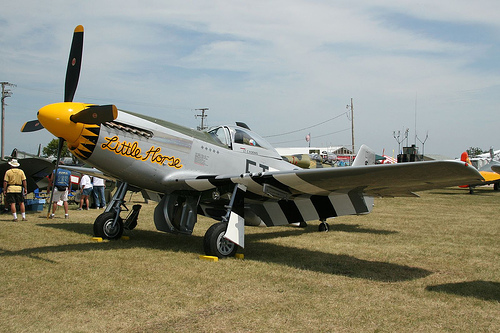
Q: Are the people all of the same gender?
A: No, they are both male and female.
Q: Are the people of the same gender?
A: No, they are both male and female.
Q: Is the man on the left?
A: Yes, the man is on the left of the image.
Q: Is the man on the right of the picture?
A: No, the man is on the left of the image.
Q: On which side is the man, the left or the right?
A: The man is on the left of the image.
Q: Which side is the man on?
A: The man is on the left of the image.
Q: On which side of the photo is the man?
A: The man is on the left of the image.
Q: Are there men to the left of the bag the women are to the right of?
A: Yes, there is a man to the left of the bag.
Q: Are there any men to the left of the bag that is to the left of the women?
A: Yes, there is a man to the left of the bag.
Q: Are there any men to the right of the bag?
A: No, the man is to the left of the bag.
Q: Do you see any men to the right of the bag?
A: No, the man is to the left of the bag.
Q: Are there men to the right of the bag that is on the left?
A: No, the man is to the left of the bag.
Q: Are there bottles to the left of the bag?
A: No, there is a man to the left of the bag.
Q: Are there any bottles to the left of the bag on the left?
A: No, there is a man to the left of the bag.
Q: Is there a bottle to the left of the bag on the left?
A: No, there is a man to the left of the bag.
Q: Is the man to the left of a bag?
A: Yes, the man is to the left of a bag.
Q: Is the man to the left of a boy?
A: No, the man is to the left of a bag.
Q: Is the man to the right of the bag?
A: No, the man is to the left of the bag.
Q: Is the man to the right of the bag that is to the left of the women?
A: No, the man is to the left of the bag.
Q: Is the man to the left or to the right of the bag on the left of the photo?
A: The man is to the left of the bag.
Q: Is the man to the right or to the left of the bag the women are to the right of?
A: The man is to the left of the bag.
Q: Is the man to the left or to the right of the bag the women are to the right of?
A: The man is to the left of the bag.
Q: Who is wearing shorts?
A: The man is wearing shorts.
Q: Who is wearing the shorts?
A: The man is wearing shorts.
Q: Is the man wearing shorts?
A: Yes, the man is wearing shorts.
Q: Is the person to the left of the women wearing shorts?
A: Yes, the man is wearing shorts.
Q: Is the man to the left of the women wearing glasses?
A: No, the man is wearing shorts.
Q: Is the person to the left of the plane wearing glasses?
A: No, the man is wearing shorts.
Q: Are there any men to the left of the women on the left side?
A: Yes, there is a man to the left of the women.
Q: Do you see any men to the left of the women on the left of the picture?
A: Yes, there is a man to the left of the women.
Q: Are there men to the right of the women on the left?
A: No, the man is to the left of the women.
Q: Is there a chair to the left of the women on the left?
A: No, there is a man to the left of the women.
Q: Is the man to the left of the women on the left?
A: Yes, the man is to the left of the women.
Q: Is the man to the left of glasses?
A: No, the man is to the left of the women.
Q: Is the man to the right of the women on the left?
A: No, the man is to the left of the women.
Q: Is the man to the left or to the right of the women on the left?
A: The man is to the left of the women.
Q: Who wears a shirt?
A: The man wears a shirt.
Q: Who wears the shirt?
A: The man wears a shirt.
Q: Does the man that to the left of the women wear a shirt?
A: Yes, the man wears a shirt.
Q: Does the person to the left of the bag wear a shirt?
A: Yes, the man wears a shirt.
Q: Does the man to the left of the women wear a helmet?
A: No, the man wears a shirt.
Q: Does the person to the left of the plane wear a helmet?
A: No, the man wears a shirt.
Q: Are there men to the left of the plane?
A: Yes, there is a man to the left of the plane.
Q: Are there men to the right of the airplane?
A: No, the man is to the left of the airplane.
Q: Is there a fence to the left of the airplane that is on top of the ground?
A: No, there is a man to the left of the plane.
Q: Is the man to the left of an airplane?
A: Yes, the man is to the left of an airplane.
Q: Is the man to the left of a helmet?
A: No, the man is to the left of an airplane.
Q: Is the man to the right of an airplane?
A: No, the man is to the left of an airplane.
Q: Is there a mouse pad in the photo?
A: No, there are no mouse pads.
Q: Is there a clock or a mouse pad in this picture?
A: No, there are no mouse pads or clocks.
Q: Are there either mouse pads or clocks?
A: No, there are no mouse pads or clocks.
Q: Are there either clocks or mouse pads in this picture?
A: No, there are no mouse pads or clocks.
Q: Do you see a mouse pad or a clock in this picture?
A: No, there are no mouse pads or clocks.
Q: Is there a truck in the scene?
A: No, there are no trucks.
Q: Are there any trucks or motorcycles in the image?
A: No, there are no trucks or motorcycles.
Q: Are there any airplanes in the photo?
A: Yes, there is an airplane.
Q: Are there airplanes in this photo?
A: Yes, there is an airplane.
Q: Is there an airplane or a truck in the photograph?
A: Yes, there is an airplane.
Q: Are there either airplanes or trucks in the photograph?
A: Yes, there is an airplane.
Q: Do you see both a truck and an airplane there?
A: No, there is an airplane but no trucks.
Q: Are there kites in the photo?
A: No, there are no kites.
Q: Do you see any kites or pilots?
A: No, there are no kites or pilots.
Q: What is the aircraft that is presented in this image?
A: The aircraft is an airplane.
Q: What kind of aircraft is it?
A: The aircraft is an airplane.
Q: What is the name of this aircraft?
A: This is an airplane.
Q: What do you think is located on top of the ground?
A: The airplane is on top of the ground.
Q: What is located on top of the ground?
A: The airplane is on top of the ground.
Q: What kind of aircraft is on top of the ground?
A: The aircraft is an airplane.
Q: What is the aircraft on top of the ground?
A: The aircraft is an airplane.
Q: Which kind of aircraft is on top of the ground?
A: The aircraft is an airplane.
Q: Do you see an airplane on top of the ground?
A: Yes, there is an airplane on top of the ground.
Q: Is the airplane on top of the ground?
A: Yes, the airplane is on top of the ground.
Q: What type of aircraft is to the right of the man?
A: The aircraft is an airplane.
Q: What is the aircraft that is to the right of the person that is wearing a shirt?
A: The aircraft is an airplane.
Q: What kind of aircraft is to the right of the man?
A: The aircraft is an airplane.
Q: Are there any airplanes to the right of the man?
A: Yes, there is an airplane to the right of the man.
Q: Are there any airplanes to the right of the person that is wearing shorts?
A: Yes, there is an airplane to the right of the man.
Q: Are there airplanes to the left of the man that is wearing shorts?
A: No, the airplane is to the right of the man.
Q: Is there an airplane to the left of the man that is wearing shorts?
A: No, the airplane is to the right of the man.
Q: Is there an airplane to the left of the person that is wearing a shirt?
A: No, the airplane is to the right of the man.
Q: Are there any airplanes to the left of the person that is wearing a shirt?
A: No, the airplane is to the right of the man.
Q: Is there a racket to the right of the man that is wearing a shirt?
A: No, there is an airplane to the right of the man.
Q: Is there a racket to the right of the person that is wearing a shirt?
A: No, there is an airplane to the right of the man.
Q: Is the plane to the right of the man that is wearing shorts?
A: Yes, the plane is to the right of the man.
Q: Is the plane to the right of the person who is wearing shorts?
A: Yes, the plane is to the right of the man.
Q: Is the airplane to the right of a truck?
A: No, the airplane is to the right of the man.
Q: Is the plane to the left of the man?
A: No, the plane is to the right of the man.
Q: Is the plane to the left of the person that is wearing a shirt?
A: No, the plane is to the right of the man.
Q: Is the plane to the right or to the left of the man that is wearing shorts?
A: The plane is to the right of the man.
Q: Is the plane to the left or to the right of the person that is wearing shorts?
A: The plane is to the right of the man.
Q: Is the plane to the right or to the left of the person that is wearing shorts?
A: The plane is to the right of the man.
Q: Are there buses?
A: No, there are no buses.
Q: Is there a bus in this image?
A: No, there are no buses.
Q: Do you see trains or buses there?
A: No, there are no buses or trains.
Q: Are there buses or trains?
A: No, there are no buses or trains.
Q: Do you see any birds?
A: No, there are no birds.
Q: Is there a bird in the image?
A: No, there are no birds.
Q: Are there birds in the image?
A: No, there are no birds.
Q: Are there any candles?
A: No, there are no candles.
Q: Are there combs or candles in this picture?
A: No, there are no candles or combs.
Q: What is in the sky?
A: The clouds are in the sky.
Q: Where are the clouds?
A: The clouds are in the sky.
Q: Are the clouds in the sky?
A: Yes, the clouds are in the sky.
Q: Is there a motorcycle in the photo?
A: No, there are no motorcycles.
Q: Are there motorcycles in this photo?
A: No, there are no motorcycles.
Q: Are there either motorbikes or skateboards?
A: No, there are no motorbikes or skateboards.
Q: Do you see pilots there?
A: No, there are no pilots.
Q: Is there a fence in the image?
A: No, there are no fences.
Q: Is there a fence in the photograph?
A: No, there are no fences.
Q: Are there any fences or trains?
A: No, there are no fences or trains.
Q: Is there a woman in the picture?
A: Yes, there are women.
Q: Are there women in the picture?
A: Yes, there are women.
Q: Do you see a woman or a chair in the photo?
A: Yes, there are women.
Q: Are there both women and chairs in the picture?
A: No, there are women but no chairs.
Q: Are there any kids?
A: No, there are no kids.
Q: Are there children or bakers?
A: No, there are no children or bakers.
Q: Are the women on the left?
A: Yes, the women are on the left of the image.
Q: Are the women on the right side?
A: No, the women are on the left of the image.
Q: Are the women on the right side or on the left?
A: The women are on the left of the image.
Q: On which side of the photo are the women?
A: The women are on the left of the image.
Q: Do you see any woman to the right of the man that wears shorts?
A: Yes, there are women to the right of the man.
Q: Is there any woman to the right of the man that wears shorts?
A: Yes, there are women to the right of the man.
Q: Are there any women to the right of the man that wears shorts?
A: Yes, there are women to the right of the man.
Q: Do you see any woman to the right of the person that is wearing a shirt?
A: Yes, there are women to the right of the man.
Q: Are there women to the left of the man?
A: No, the women are to the right of the man.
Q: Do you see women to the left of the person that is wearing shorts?
A: No, the women are to the right of the man.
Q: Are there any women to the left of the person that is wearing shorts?
A: No, the women are to the right of the man.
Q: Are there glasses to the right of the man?
A: No, there are women to the right of the man.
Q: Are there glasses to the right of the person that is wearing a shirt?
A: No, there are women to the right of the man.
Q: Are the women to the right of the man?
A: Yes, the women are to the right of the man.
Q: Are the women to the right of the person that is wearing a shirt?
A: Yes, the women are to the right of the man.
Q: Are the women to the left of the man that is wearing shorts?
A: No, the women are to the right of the man.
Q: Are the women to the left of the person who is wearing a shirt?
A: No, the women are to the right of the man.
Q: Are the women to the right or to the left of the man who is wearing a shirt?
A: The women are to the right of the man.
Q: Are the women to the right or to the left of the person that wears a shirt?
A: The women are to the right of the man.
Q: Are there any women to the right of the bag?
A: Yes, there are women to the right of the bag.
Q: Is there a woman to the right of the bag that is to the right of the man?
A: Yes, there are women to the right of the bag.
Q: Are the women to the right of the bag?
A: Yes, the women are to the right of the bag.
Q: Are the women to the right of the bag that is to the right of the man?
A: Yes, the women are to the right of the bag.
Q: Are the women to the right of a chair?
A: No, the women are to the right of the bag.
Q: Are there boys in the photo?
A: No, there are no boys.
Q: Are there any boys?
A: No, there are no boys.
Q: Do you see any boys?
A: No, there are no boys.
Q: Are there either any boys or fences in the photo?
A: No, there are no boys or fences.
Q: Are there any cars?
A: No, there are no cars.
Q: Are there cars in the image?
A: No, there are no cars.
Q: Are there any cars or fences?
A: No, there are no cars or fences.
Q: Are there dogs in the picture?
A: No, there are no dogs.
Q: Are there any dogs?
A: No, there are no dogs.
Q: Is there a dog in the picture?
A: No, there are no dogs.